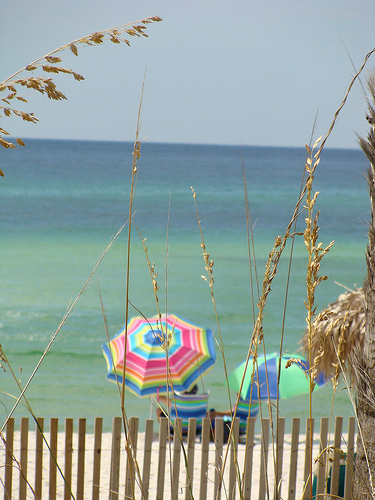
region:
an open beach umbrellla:
[101, 312, 217, 393]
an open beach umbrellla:
[224, 351, 332, 399]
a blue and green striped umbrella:
[225, 353, 335, 398]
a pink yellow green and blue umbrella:
[100, 312, 217, 397]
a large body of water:
[2, 138, 370, 433]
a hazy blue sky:
[0, 0, 373, 148]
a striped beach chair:
[169, 393, 209, 441]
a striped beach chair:
[231, 400, 256, 442]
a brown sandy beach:
[3, 430, 358, 498]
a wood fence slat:
[5, 415, 13, 498]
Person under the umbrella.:
[119, 308, 220, 430]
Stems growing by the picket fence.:
[233, 276, 295, 483]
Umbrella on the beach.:
[226, 344, 323, 413]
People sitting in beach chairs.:
[168, 381, 266, 443]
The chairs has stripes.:
[171, 387, 254, 430]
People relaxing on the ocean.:
[107, 318, 299, 439]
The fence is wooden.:
[61, 423, 295, 498]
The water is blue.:
[79, 135, 293, 213]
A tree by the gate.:
[321, 224, 374, 378]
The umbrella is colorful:
[106, 299, 200, 386]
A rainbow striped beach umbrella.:
[99, 309, 216, 398]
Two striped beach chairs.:
[153, 390, 256, 435]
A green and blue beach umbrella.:
[223, 350, 328, 400]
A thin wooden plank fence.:
[2, 415, 369, 494]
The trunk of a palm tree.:
[350, 75, 370, 499]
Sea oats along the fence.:
[0, 1, 370, 496]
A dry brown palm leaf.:
[300, 277, 367, 382]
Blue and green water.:
[0, 138, 370, 419]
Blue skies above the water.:
[1, 5, 369, 156]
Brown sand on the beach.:
[0, 426, 362, 495]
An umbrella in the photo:
[100, 315, 217, 397]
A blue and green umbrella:
[215, 344, 333, 411]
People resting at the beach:
[170, 386, 264, 431]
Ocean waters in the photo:
[172, 179, 271, 243]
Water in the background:
[151, 130, 257, 172]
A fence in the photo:
[188, 426, 298, 490]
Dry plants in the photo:
[233, 268, 359, 420]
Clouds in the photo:
[211, 46, 303, 100]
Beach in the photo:
[160, 462, 255, 486]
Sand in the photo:
[118, 435, 282, 481]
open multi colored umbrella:
[111, 313, 205, 397]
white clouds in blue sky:
[16, 138, 80, 201]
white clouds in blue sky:
[17, 255, 65, 300]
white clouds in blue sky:
[174, 169, 229, 210]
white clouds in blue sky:
[182, 93, 216, 121]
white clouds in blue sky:
[222, 42, 269, 89]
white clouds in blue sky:
[152, 68, 186, 108]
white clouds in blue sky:
[337, 176, 358, 229]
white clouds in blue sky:
[74, 87, 120, 135]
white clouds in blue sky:
[26, 14, 47, 40]